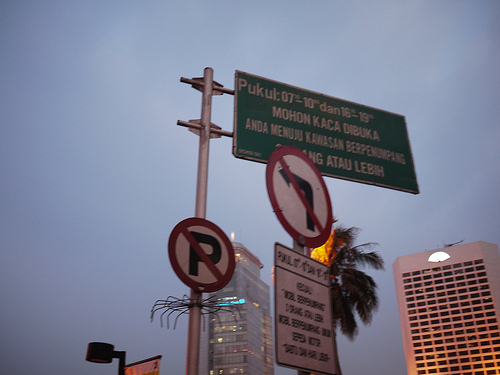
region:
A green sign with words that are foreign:
[221, 59, 414, 141]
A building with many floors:
[396, 233, 493, 373]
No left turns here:
[263, 138, 341, 269]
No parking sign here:
[158, 211, 236, 294]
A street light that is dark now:
[89, 334, 136, 371]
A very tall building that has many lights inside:
[203, 242, 271, 366]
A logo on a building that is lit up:
[420, 247, 449, 267]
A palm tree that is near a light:
[311, 245, 382, 349]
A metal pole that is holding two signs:
[172, 56, 224, 373]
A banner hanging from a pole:
[113, 354, 170, 373]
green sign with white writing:
[226, 59, 433, 202]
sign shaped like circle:
[163, 203, 245, 301]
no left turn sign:
[264, 139, 339, 251]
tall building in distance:
[369, 229, 496, 373]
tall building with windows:
[197, 216, 279, 373]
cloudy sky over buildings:
[4, 4, 498, 329]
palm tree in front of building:
[319, 198, 389, 373]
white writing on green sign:
[242, 75, 409, 181]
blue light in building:
[214, 294, 249, 308]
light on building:
[425, 244, 455, 264]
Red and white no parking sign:
[160, 211, 240, 294]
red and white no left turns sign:
[265, 138, 337, 243]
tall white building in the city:
[389, 238, 498, 374]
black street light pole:
[75, 334, 127, 374]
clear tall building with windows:
[208, 229, 270, 373]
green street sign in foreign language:
[235, 55, 437, 199]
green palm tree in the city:
[293, 212, 386, 339]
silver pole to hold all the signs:
[169, 50, 234, 374]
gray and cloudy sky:
[10, 14, 498, 200]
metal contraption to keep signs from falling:
[147, 288, 247, 333]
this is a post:
[178, 67, 228, 205]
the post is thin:
[188, 58, 226, 196]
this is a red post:
[169, 220, 236, 284]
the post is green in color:
[340, 110, 402, 177]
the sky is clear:
[23, 61, 147, 249]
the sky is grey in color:
[6, 13, 160, 267]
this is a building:
[408, 249, 483, 368]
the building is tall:
[430, 244, 480, 373]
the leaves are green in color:
[338, 235, 382, 327]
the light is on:
[314, 247, 334, 266]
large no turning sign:
[240, 122, 365, 279]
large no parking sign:
[163, 214, 269, 301]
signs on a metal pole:
[177, 37, 257, 371]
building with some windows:
[401, 235, 498, 367]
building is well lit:
[402, 302, 494, 370]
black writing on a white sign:
[266, 266, 353, 373]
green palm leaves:
[310, 227, 410, 362]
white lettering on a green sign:
[233, 67, 426, 190]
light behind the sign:
[303, 224, 360, 280]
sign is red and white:
[168, 216, 245, 284]